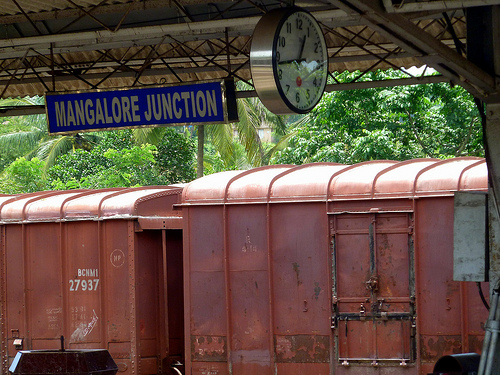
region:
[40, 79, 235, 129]
blue sign reading "mangalore junction"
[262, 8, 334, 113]
a clock reading 12:43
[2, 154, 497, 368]
red-orange train cars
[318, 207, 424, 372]
locked, rusted door to a train car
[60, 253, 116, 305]
writing on a train car that says "BCNM1 27937"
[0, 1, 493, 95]
awning over a train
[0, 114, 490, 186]
greenery along a train track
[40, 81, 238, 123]
blue sign with train stop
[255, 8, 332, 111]
overhead clock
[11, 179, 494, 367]
red, rusted train cars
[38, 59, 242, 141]
a sign for mangalore junction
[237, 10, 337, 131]
a large metal clock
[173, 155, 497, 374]
an old train car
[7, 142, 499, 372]
a set of red train cars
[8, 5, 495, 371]
an old train station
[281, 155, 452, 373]
a train car door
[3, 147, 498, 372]
an old and rundown train car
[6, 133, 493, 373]
a set of freight train cars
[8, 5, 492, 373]
a small train station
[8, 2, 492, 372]
train station at mangalore junction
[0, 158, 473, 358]
the train is red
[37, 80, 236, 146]
the sign is blue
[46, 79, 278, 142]
the sign says magalore junction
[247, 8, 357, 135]
the clock is silver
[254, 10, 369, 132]
the time says 12:44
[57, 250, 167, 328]
the train has white numbers and letters on it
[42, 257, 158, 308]
the numbers say 27937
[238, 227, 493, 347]
the paint on train is chipping off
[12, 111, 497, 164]
the trees leaves are green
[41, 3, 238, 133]
the sign is hanging from ceiling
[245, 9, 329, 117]
A large silver clock.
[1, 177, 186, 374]
A faded red train car on the back end of a train.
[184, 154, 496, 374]
A faded red train car on the right side.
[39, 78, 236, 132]
A blue sign that says MANGALORE JUNCTION.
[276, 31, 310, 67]
Black hands on a clock face.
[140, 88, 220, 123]
The word JUNCTION.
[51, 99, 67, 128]
The letter M on a blue sign.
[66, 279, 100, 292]
The number 27937 on the side of a train.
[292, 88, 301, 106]
The number 6 on a clock face.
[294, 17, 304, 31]
A black number 12.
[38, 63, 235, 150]
blue sign next to clock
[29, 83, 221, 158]
blue sign with white writing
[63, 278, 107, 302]
the number 27937 in white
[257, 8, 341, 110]
clock hanging from ceiling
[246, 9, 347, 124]
silver clock with white face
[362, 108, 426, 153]
green trees in background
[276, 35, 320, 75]
black hands of the clock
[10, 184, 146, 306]
red structure outdoors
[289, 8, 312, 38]
the number twelve on clock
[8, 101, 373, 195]
many trees in background